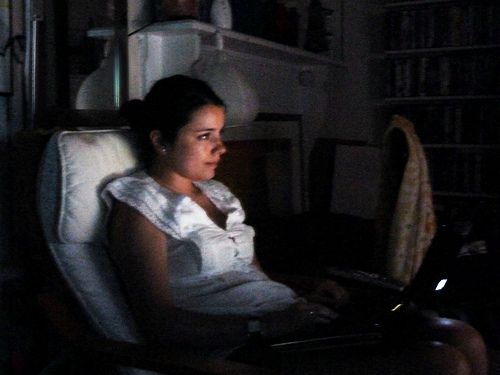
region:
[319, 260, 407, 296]
TV Remote on the arm of the couch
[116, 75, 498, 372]
Woman watching tv working on her computer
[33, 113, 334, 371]
White Upright Lounge Chair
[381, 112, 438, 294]
Blanket Hang Over A Chair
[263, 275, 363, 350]
Woman's hands on her computer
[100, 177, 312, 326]
White Short Sleeve Blouse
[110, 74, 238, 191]
Woman's hair is in a ponytail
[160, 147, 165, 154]
Small Diamond Earring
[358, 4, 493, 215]
Shelves containing alot of books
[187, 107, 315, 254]
Unused White Fireplace with brown frame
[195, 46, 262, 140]
light beside the woman's head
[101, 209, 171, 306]
the woman's right arm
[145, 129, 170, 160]
the woman's right ear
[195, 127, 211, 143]
the woman's right eye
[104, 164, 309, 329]
the woman's white shirt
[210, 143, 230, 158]
the woman's nose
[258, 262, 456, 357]
lap top in the woman's lap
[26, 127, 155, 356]
white pillows behind the woman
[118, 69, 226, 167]
the woman's dark hair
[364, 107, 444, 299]
colorful blanket near the woman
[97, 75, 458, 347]
woman sitting white chair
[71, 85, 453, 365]
woman playing on computer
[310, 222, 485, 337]
lap top computer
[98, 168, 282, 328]
white blouse on woman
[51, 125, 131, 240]
white pillow from white chair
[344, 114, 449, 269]
sheet hangign from chair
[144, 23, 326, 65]
white wooden shelf in background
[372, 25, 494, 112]
books lined up on shelves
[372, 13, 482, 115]
shelves filled with books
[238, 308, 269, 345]
black watch on wrist of woman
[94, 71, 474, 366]
Woman is sitting down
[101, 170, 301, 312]
Woman is wearing a shirt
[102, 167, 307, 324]
Woman is wearing a white shirt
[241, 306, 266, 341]
Woman is wearing a watch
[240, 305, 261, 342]
Woman is wearing a black watch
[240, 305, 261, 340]
Woman is wearing a black wrist watch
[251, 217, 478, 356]
Woman is on the laptop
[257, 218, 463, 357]
Laptop on woman's lap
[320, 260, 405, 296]
Remote control next to woman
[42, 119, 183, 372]
Chair cushion is white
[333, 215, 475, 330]
laptop computer on woman's lap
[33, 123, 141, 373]
back of white IKEA chair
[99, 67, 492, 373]
woman sitting using laptop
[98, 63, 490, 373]
woman wearing white shirt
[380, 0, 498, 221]
bookshelf on the wall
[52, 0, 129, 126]
mirror with dark frame on the wall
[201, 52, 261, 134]
white lamp below shelf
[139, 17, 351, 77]
white shelf against the wall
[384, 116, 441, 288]
yellow blanket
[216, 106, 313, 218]
fireplace against the wall